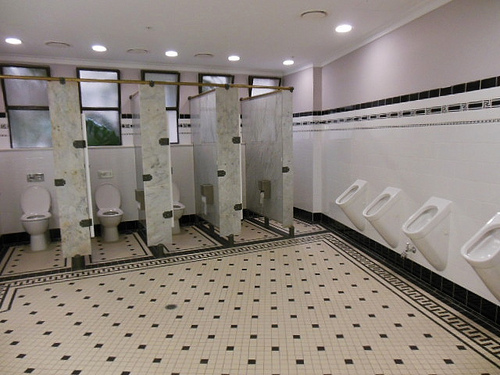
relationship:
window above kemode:
[0, 60, 52, 147] [19, 187, 51, 252]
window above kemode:
[81, 110, 121, 147] [95, 183, 124, 242]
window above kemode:
[139, 67, 180, 148] [170, 179, 185, 239]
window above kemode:
[200, 75, 234, 93] [19, 187, 51, 252]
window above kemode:
[250, 75, 281, 99] [95, 183, 124, 242]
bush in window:
[82, 117, 121, 145] [75, 67, 134, 154]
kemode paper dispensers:
[19, 186, 51, 252] [196, 182, 213, 207]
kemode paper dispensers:
[94, 182, 124, 242] [131, 190, 146, 212]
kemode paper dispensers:
[172, 179, 184, 234] [260, 173, 270, 201]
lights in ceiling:
[4, 23, 355, 73] [166, 17, 294, 47]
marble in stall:
[129, 79, 175, 253] [129, 85, 174, 247]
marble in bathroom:
[129, 79, 175, 253] [2, 4, 497, 373]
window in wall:
[55, 54, 139, 148] [319, 50, 496, 185]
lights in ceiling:
[334, 23, 352, 33] [4, 0, 321, 70]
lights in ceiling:
[282, 49, 293, 67] [4, 0, 321, 70]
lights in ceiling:
[228, 52, 244, 62] [4, 0, 321, 70]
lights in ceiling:
[163, 37, 174, 57] [4, 0, 321, 70]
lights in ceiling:
[93, 37, 105, 52] [4, 0, 321, 70]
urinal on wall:
[460, 213, 500, 304] [352, 108, 480, 146]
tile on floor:
[403, 312, 418, 321] [11, 262, 441, 374]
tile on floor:
[405, 339, 421, 354] [11, 262, 441, 374]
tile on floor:
[251, 297, 261, 304] [11, 262, 441, 374]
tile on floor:
[182, 295, 192, 305] [11, 262, 441, 374]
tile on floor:
[206, 332, 215, 344] [11, 262, 441, 374]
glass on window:
[8, 107, 50, 147] [0, 60, 52, 147]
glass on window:
[8, 107, 50, 147] [81, 110, 121, 147]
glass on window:
[2, 62, 48, 104] [142, 69, 178, 145]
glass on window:
[2, 62, 48, 104] [201, 73, 231, 94]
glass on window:
[8, 107, 50, 147] [251, 74, 276, 94]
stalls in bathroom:
[227, 90, 284, 231] [2, 4, 497, 373]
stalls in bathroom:
[166, 84, 209, 241] [2, 4, 497, 373]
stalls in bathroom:
[81, 79, 147, 233] [2, 4, 497, 373]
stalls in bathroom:
[11, 79, 60, 247] [2, 4, 497, 373]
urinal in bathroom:
[332, 175, 370, 236] [2, 4, 497, 373]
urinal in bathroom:
[359, 180, 407, 251] [2, 4, 497, 373]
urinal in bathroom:
[397, 187, 454, 273] [2, 4, 497, 373]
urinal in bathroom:
[457, 208, 498, 303] [2, 4, 497, 373]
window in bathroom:
[250, 76, 280, 97] [32, 51, 311, 150]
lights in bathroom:
[0, 23, 360, 66] [2, 4, 497, 373]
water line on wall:
[398, 238, 418, 262] [281, 0, 499, 337]